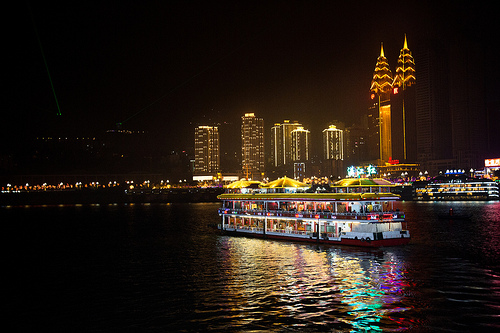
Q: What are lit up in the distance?
A: Buildings.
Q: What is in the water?
A: A boat.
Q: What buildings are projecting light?
A: Buildings in the back.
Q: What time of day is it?
A: The night.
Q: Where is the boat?
A: The water.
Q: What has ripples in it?
A: The water.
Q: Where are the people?
A: On the boat.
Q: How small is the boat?
A: Large.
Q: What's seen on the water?
A: Reflections.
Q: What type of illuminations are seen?
A: Bright neon.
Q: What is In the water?
A: Boat.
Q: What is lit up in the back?
A: Skyscrapers.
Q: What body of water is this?
A: River.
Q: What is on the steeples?
A: Christmas trees.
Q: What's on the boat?
A: Lights and decor.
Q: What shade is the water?
A: Full darkness.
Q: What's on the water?
A: Reflection of lights.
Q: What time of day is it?
A: Night.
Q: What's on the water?
A: Boat.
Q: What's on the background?
A: Buildings.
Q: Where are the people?
A: On the boat.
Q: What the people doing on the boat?
A: Partying.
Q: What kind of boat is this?
A: Tourist boat.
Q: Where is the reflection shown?
A: In the water.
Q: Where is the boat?
A: On the water.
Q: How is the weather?
A: Clear.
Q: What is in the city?
A: Lights.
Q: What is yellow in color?
A: The lights.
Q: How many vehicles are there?
A: One.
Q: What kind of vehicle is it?
A: Boat.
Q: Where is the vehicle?
A: On the water.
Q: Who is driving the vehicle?
A: A captain.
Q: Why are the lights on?
A: It's night time.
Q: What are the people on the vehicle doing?
A: Partying.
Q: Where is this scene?
A: A city.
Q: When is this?
A: At night.